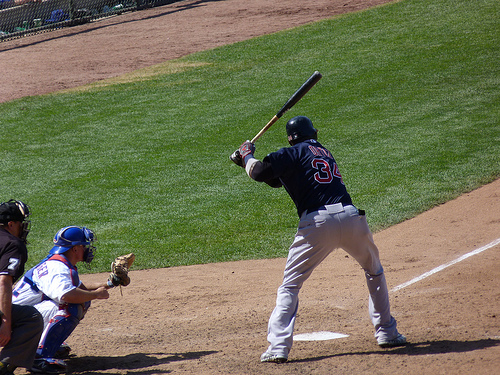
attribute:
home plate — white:
[280, 331, 355, 343]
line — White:
[418, 226, 498, 270]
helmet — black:
[278, 117, 316, 138]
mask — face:
[81, 225, 97, 262]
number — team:
[306, 143, 346, 194]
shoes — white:
[246, 321, 438, 372]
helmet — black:
[282, 108, 322, 149]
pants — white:
[232, 183, 433, 373]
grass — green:
[0, 2, 498, 275]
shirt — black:
[257, 139, 352, 208]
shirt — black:
[18, 256, 75, 312]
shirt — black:
[0, 224, 30, 286]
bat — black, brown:
[249, 69, 322, 141]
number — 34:
[298, 137, 355, 198]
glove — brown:
[111, 254, 134, 287]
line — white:
[435, 247, 466, 291]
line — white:
[418, 246, 492, 274]